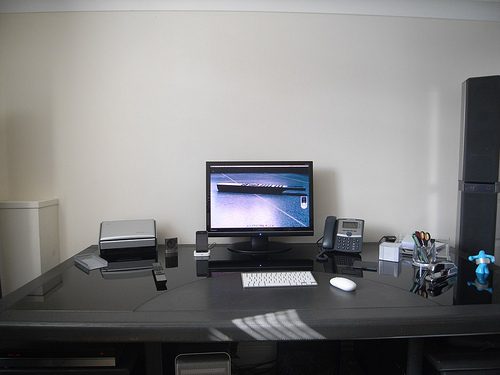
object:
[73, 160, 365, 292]
electronics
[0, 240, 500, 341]
desk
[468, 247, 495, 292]
toy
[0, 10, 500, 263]
wall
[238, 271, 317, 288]
keyboard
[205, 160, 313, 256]
monitor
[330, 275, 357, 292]
mouse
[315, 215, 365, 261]
telephone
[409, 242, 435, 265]
cup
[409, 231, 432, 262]
pens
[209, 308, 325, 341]
reflection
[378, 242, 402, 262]
paper block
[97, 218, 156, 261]
printer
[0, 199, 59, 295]
cabinet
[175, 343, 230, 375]
computer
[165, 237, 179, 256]
speaker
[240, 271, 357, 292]
keyboar and mouse